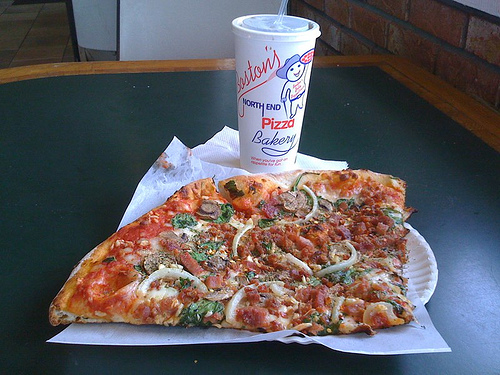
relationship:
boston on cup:
[235, 50, 282, 99] [231, 2, 321, 171]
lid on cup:
[231, 12, 323, 42] [231, 2, 321, 171]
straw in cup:
[273, 0, 289, 30] [231, 2, 321, 171]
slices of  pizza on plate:
[49, 169, 416, 337] [125, 171, 441, 344]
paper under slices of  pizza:
[47, 125, 453, 356] [49, 169, 416, 337]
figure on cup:
[276, 53, 306, 118] [231, 2, 321, 171]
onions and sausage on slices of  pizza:
[226, 222, 360, 327] [49, 169, 416, 337]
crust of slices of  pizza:
[48, 239, 108, 325] [49, 169, 416, 337]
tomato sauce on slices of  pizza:
[80, 264, 136, 316] [49, 169, 416, 337]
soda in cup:
[246, 15, 311, 33] [231, 2, 321, 171]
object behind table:
[116, 0, 289, 60] [1, 66, 498, 373]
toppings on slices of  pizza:
[139, 206, 270, 327] [49, 169, 416, 337]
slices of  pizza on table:
[49, 169, 416, 337] [1, 66, 498, 373]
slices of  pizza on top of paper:
[49, 169, 416, 337] [47, 125, 453, 356]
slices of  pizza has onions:
[49, 169, 416, 337] [141, 267, 284, 323]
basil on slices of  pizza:
[184, 296, 225, 326] [49, 169, 416, 337]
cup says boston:
[231, 2, 321, 171] [235, 50, 282, 99]